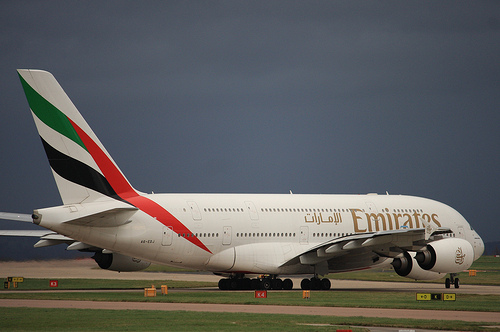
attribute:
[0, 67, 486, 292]
plane — painted green, white, painted red, large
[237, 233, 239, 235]
window — small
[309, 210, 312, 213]
window — small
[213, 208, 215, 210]
window — small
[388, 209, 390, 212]
window — small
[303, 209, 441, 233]
words — gold, arabic, brown, foreign, emirates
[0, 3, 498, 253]
sky — cloudy, dark, grey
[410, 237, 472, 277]
engine — black white andgold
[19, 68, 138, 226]
stabilizer — vertical, green black, red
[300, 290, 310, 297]
sign — orange